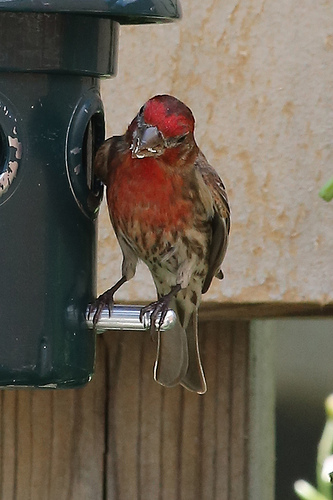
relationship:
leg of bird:
[84, 248, 139, 329] [84, 94, 228, 393]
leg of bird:
[137, 249, 199, 337] [84, 94, 228, 393]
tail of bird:
[150, 264, 208, 397] [84, 94, 228, 393]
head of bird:
[124, 93, 202, 170] [84, 94, 228, 393]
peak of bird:
[129, 115, 172, 162] [84, 94, 228, 393]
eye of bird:
[135, 105, 149, 120] [84, 94, 228, 393]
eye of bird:
[176, 131, 188, 146] [84, 94, 228, 393]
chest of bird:
[110, 137, 199, 277] [84, 94, 228, 393]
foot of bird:
[81, 274, 130, 336] [84, 94, 228, 393]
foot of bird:
[140, 282, 181, 342] [84, 94, 228, 393]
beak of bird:
[130, 112, 179, 164] [84, 94, 228, 393]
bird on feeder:
[84, 94, 228, 393] [0, 1, 182, 389]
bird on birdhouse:
[84, 94, 228, 393] [1, 2, 177, 389]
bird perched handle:
[84, 94, 228, 393] [87, 307, 178, 333]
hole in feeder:
[0, 127, 7, 178] [0, 1, 182, 389]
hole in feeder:
[81, 112, 107, 196] [0, 1, 182, 389]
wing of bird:
[95, 135, 117, 187] [84, 94, 228, 393]